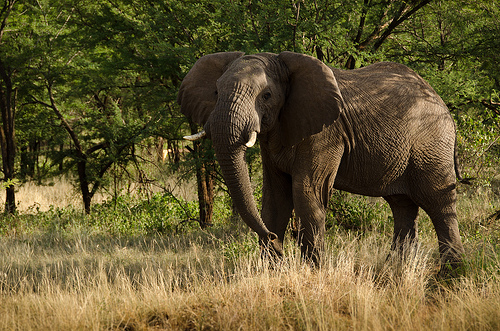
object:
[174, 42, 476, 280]
elephant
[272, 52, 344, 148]
ears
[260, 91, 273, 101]
black eye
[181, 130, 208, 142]
tusk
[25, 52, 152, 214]
tree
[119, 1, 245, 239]
tree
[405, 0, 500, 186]
tree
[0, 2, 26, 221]
tree